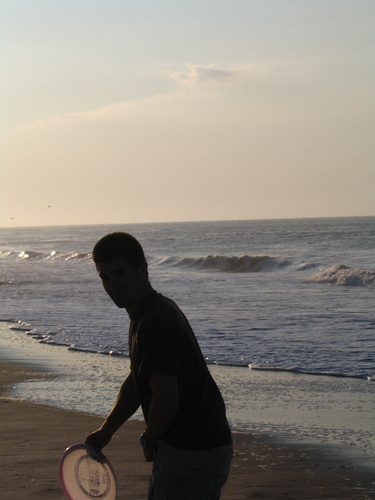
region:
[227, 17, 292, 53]
part of the sky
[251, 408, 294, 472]
part of the shore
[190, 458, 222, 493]
part of a short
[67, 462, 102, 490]
part of a dish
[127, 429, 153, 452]
part of a watch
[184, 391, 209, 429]
part of a top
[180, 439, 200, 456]
edge of a top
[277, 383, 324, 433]
part of the shore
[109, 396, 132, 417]
part of an arm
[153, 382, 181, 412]
part of an elbow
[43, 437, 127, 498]
frisbee is clear and see through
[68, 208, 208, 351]
A guy on the beach.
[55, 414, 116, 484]
Frisbee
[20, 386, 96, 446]
Sand on the beach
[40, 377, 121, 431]
Waves on the sand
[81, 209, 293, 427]
Waves behind the man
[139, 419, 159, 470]
watch on the wrist.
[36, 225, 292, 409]
Playing on the beach in the sand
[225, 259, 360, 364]
The ocean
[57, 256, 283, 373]
Boy playing Frisbee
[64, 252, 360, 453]
On the beach playing a game of Frisbee.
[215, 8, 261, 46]
part of the sky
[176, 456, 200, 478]
part of short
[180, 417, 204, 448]
part of a top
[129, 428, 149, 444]
part of a watch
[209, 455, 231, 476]
part of a pocket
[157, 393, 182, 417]
part of an elbow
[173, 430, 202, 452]
edge of a shirt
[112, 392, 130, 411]
part of an arm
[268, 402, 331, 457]
part of a shore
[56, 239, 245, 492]
One man is seen.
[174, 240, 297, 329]
Waves are white color.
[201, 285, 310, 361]
Water is blue color.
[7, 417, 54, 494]
Sand is brown color.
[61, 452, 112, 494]
Frisbee is pink color.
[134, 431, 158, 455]
Man is wearing watch.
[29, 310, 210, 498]
Man is holding Frisbee.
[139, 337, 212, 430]
Man is wearing brown shirt.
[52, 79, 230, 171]
Sky is white color.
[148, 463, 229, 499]
Man is wearing grey pant.